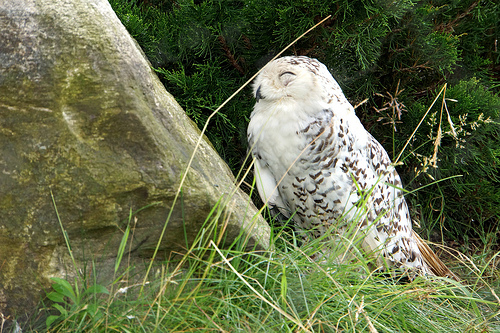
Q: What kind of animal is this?
A: A bird.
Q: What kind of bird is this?
A: An owl.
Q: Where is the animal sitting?
A: On the ground.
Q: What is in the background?
A: Trees.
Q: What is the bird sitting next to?
A: A big rock.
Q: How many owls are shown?
A: One.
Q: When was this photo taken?
A: During the daytime.